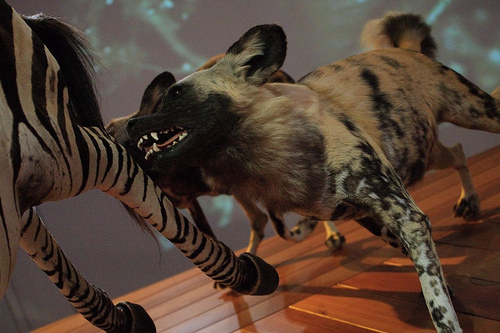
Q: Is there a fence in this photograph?
A: No, there are no fences.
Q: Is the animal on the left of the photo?
A: Yes, the animal is on the left of the image.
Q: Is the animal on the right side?
A: No, the animal is on the left of the image.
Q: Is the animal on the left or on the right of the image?
A: The animal is on the left of the image.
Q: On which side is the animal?
A: The animal is on the left of the image.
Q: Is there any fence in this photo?
A: No, there are no fences.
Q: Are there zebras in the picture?
A: Yes, there is a zebra.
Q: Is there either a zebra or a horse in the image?
A: Yes, there is a zebra.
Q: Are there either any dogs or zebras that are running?
A: Yes, the zebra is running.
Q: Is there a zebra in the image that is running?
A: Yes, there is a zebra that is running.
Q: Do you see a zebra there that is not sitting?
A: Yes, there is a zebra that is running .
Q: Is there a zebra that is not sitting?
A: Yes, there is a zebra that is running.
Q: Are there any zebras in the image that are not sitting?
A: Yes, there is a zebra that is running.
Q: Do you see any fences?
A: No, there are no fences.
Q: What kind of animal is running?
A: The animal is a zebra.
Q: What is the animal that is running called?
A: The animal is a zebra.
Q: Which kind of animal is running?
A: The animal is a zebra.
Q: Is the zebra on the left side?
A: Yes, the zebra is on the left of the image.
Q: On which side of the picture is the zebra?
A: The zebra is on the left of the image.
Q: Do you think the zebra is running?
A: Yes, the zebra is running.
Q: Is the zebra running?
A: Yes, the zebra is running.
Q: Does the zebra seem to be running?
A: Yes, the zebra is running.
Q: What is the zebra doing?
A: The zebra is running.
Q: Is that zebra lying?
A: No, the zebra is running.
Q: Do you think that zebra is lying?
A: No, the zebra is running.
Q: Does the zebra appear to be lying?
A: No, the zebra is running.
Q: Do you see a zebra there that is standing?
A: No, there is a zebra but it is running.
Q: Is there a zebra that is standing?
A: No, there is a zebra but it is running.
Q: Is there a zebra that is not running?
A: No, there is a zebra but it is running.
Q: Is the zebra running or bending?
A: The zebra is running.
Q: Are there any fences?
A: No, there are no fences.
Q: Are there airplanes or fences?
A: No, there are no fences or airplanes.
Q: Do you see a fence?
A: No, there are no fences.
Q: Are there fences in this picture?
A: No, there are no fences.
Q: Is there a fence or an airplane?
A: No, there are no fences or airplanes.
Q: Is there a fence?
A: No, there are no fences.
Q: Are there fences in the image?
A: No, there are no fences.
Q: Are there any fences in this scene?
A: No, there are no fences.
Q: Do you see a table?
A: Yes, there is a table.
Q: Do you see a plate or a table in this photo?
A: Yes, there is a table.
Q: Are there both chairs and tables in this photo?
A: No, there is a table but no chairs.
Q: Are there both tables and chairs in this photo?
A: No, there is a table but no chairs.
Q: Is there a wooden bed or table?
A: Yes, there is a wood table.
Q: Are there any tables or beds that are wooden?
A: Yes, the table is wooden.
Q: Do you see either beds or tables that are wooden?
A: Yes, the table is wooden.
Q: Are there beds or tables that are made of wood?
A: Yes, the table is made of wood.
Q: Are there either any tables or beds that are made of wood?
A: Yes, the table is made of wood.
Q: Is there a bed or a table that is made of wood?
A: Yes, the table is made of wood.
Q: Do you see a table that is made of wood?
A: Yes, there is a table that is made of wood.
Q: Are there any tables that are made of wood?
A: Yes, there is a table that is made of wood.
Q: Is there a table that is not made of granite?
A: Yes, there is a table that is made of wood.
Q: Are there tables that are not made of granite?
A: Yes, there is a table that is made of wood.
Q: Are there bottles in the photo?
A: No, there are no bottles.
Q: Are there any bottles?
A: No, there are no bottles.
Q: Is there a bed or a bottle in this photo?
A: No, there are no bottles or beds.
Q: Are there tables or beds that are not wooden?
A: No, there is a table but it is wooden.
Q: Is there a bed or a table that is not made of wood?
A: No, there is a table but it is made of wood.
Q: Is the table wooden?
A: Yes, the table is wooden.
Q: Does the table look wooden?
A: Yes, the table is wooden.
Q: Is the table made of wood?
A: Yes, the table is made of wood.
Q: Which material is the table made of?
A: The table is made of wood.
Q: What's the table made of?
A: The table is made of wood.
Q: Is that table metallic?
A: No, the table is wooden.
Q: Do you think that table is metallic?
A: No, the table is wooden.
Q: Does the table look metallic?
A: No, the table is wooden.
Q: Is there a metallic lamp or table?
A: No, there is a table but it is wooden.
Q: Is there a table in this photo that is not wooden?
A: No, there is a table but it is wooden.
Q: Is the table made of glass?
A: No, the table is made of wood.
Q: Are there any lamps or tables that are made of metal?
A: No, there is a table but it is made of wood.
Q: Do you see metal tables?
A: No, there is a table but it is made of wood.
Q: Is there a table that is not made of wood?
A: No, there is a table but it is made of wood.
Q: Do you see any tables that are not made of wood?
A: No, there is a table but it is made of wood.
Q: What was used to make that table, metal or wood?
A: The table is made of wood.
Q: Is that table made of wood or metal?
A: The table is made of wood.